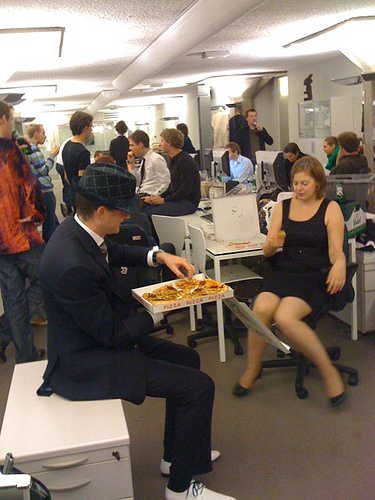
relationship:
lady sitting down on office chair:
[233, 155, 346, 408] [289, 353, 308, 399]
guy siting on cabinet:
[39, 154, 243, 500] [0, 360, 132, 495]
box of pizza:
[129, 267, 290, 353] [144, 276, 222, 306]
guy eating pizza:
[125, 125, 171, 216] [123, 145, 136, 157]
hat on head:
[72, 160, 149, 217] [58, 158, 153, 241]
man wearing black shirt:
[141, 125, 202, 217] [155, 151, 201, 205]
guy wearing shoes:
[39, 154, 243, 500] [161, 448, 233, 497]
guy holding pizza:
[39, 154, 243, 500] [137, 271, 232, 315]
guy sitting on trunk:
[39, 154, 243, 500] [0, 359, 135, 498]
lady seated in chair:
[233, 155, 346, 408] [289, 253, 363, 394]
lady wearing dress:
[233, 155, 346, 408] [266, 197, 345, 308]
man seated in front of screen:
[252, 137, 321, 196] [252, 145, 284, 185]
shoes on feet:
[157, 450, 246, 498] [157, 440, 230, 497]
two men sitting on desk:
[127, 125, 207, 233] [151, 206, 281, 364]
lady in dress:
[233, 155, 346, 408] [253, 197, 331, 312]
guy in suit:
[39, 161, 246, 499] [35, 212, 219, 471]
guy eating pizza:
[39, 161, 246, 499] [146, 268, 221, 309]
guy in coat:
[39, 161, 246, 499] [234, 126, 276, 157]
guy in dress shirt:
[122, 133, 158, 168] [137, 153, 166, 196]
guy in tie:
[122, 133, 158, 168] [137, 160, 147, 183]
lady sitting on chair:
[233, 155, 346, 408] [326, 222, 367, 393]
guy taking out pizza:
[39, 161, 246, 499] [144, 275, 225, 304]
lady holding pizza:
[233, 155, 346, 408] [268, 223, 293, 256]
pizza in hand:
[268, 223, 293, 256] [266, 233, 292, 253]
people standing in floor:
[5, 111, 100, 357] [241, 420, 366, 490]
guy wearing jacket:
[39, 154, 243, 500] [34, 212, 159, 409]